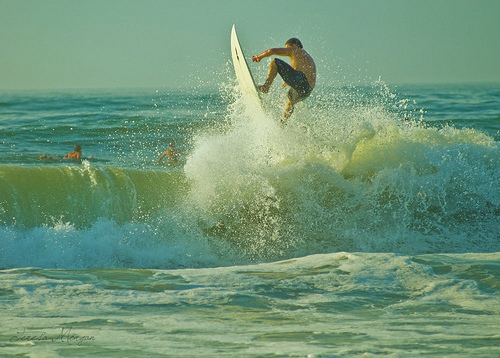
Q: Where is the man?
A: At the ocean.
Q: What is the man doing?
A: Surfing.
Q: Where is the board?
A: Below the man.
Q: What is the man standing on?
A: The board.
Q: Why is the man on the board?
A: To surf.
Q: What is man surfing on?
A: Board.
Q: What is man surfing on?
A: Board.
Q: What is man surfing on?
A: Ocean.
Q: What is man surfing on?
A: Board.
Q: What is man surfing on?
A: Board.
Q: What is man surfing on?
A: Wave.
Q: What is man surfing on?
A: Board.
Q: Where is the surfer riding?
A: On a wave.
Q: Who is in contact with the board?
A: A surfer.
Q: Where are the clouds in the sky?
A: There are none.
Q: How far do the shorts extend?
A: To the man's knees.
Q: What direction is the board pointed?
A: Up.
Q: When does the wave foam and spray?
A: After it crests.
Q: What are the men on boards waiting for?
A: The next wave.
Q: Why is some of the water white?
A: A wave crashed.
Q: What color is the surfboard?
A: White.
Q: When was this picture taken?
A: Daytime.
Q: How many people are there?
A: Three.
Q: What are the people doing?
A: Surfing.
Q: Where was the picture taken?
A: At the beach.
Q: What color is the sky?
A: Blue.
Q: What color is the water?
A: Green.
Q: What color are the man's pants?
A: Black.